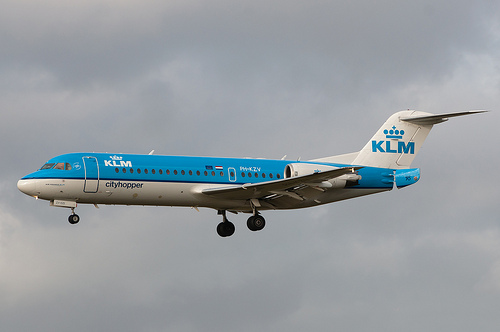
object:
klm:
[371, 140, 416, 154]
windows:
[137, 168, 142, 173]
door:
[82, 156, 101, 194]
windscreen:
[41, 161, 73, 171]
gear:
[68, 214, 81, 225]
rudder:
[403, 109, 488, 123]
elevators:
[419, 117, 449, 124]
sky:
[0, 0, 497, 332]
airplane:
[17, 107, 489, 237]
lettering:
[104, 160, 133, 168]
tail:
[308, 107, 489, 166]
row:
[114, 167, 226, 177]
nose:
[17, 173, 34, 193]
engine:
[283, 163, 363, 187]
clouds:
[0, 0, 498, 108]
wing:
[200, 166, 367, 200]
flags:
[215, 165, 224, 170]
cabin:
[32, 155, 75, 177]